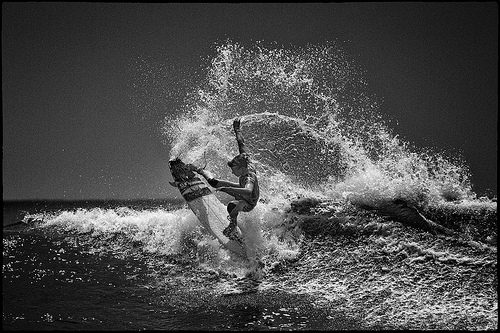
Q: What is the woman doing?
A: Surfing.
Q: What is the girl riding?
A: Wave.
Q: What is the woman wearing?
A: Bathing suit.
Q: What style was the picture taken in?
A: Black and white.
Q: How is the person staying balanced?
A: Arms in the air.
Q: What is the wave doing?
A: Crashing.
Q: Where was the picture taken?
A: In the ocean.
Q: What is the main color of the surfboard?
A: White.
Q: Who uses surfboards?
A: Surfers.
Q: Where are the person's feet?
A: In the air.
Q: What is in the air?
A: Water.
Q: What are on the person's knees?
A: Kneepads.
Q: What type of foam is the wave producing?
A: White.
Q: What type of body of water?
A: An ocean.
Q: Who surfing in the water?
A: A man.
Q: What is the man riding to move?
A: A wave.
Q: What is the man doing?
A: Surfing.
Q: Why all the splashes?
A: Water wave hit.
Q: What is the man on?
A: Surfboard.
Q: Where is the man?
A: In water.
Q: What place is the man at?
A: A beach.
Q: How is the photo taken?
A: Black and white.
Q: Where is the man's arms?
A: Up in air.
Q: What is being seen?
A: One surfing boat.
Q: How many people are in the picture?
A: One.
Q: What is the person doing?
A: Surfing.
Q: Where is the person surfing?
A: At sea.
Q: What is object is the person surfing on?
A: Surfboard.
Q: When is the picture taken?
A: Daytime.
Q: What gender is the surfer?
A: Male.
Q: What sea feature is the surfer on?
A: Waves.